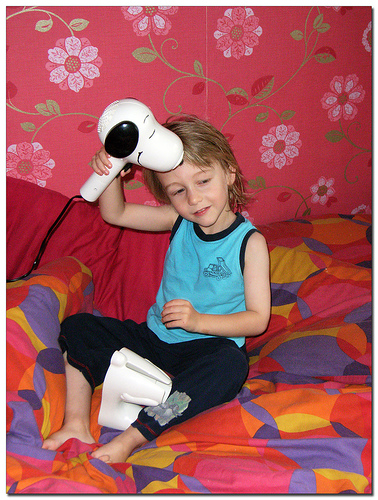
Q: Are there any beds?
A: Yes, there is a bed.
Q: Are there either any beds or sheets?
A: Yes, there is a bed.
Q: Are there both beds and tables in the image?
A: No, there is a bed but no tables.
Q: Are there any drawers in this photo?
A: No, there are no drawers.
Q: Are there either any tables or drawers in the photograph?
A: No, there are no drawers or tables.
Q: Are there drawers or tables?
A: No, there are no drawers or tables.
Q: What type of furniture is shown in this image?
A: The furniture is a bed.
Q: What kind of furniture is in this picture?
A: The furniture is a bed.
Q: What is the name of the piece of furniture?
A: The piece of furniture is a bed.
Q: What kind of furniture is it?
A: The piece of furniture is a bed.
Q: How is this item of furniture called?
A: This is a bed.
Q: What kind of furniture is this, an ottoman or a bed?
A: This is a bed.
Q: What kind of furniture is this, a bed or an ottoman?
A: This is a bed.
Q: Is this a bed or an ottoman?
A: This is a bed.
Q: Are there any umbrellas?
A: No, there are no umbrellas.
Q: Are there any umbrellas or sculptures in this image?
A: No, there are no umbrellas or sculptures.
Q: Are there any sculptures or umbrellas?
A: No, there are no umbrellas or sculptures.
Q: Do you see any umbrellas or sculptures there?
A: No, there are no umbrellas or sculptures.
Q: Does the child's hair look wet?
A: Yes, the hair is wet.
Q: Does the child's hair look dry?
A: No, the hair is wet.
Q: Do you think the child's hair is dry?
A: No, the hair is wet.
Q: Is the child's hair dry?
A: No, the hair is wet.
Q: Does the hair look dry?
A: No, the hair is wet.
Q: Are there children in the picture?
A: Yes, there is a child.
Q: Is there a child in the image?
A: Yes, there is a child.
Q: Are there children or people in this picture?
A: Yes, there is a child.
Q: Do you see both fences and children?
A: No, there is a child but no fences.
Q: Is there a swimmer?
A: No, there are no swimmers.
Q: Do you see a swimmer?
A: No, there are no swimmers.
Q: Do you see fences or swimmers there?
A: No, there are no swimmers or fences.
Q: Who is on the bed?
A: The kid is on the bed.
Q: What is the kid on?
A: The kid is on the bed.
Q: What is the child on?
A: The kid is on the bed.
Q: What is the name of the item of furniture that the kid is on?
A: The piece of furniture is a bed.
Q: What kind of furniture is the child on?
A: The kid is on the bed.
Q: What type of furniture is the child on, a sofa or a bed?
A: The child is on a bed.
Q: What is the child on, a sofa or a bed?
A: The child is on a bed.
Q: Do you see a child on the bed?
A: Yes, there is a child on the bed.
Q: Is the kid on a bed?
A: Yes, the kid is on a bed.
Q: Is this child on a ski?
A: No, the child is on a bed.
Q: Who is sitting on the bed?
A: The kid is sitting on the bed.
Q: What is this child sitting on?
A: The child is sitting on the bed.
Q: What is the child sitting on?
A: The child is sitting on the bed.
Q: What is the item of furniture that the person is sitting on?
A: The piece of furniture is a bed.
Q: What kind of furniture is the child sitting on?
A: The kid is sitting on the bed.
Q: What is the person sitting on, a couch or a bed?
A: The kid is sitting on a bed.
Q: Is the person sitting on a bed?
A: Yes, the kid is sitting on a bed.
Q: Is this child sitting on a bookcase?
A: No, the child is sitting on a bed.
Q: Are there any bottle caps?
A: No, there are no bottle caps.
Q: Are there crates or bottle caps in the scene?
A: No, there are no bottle caps or crates.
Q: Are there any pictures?
A: No, there are no pictures.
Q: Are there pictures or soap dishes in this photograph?
A: No, there are no pictures or soap dishes.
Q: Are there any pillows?
A: Yes, there is a pillow.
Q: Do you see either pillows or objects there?
A: Yes, there is a pillow.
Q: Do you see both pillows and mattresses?
A: No, there is a pillow but no mattresses.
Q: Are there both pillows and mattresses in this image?
A: No, there is a pillow but no mattresses.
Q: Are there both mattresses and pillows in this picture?
A: No, there is a pillow but no mattresses.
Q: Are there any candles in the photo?
A: No, there are no candles.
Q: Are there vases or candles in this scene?
A: No, there are no candles or vases.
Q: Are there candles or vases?
A: No, there are no candles or vases.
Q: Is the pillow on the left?
A: Yes, the pillow is on the left of the image.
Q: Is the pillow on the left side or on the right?
A: The pillow is on the left of the image.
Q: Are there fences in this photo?
A: No, there are no fences.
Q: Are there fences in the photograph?
A: No, there are no fences.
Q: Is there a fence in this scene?
A: No, there are no fences.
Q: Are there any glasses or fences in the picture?
A: No, there are no fences or glasses.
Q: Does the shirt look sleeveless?
A: Yes, the shirt is sleeveless.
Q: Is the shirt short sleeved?
A: No, the shirt is sleeveless.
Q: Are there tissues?
A: No, there are no tissues.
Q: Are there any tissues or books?
A: No, there are no tissues or books.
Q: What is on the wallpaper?
A: The flower is on the wallpaper.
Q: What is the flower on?
A: The flower is on the wallpaper.